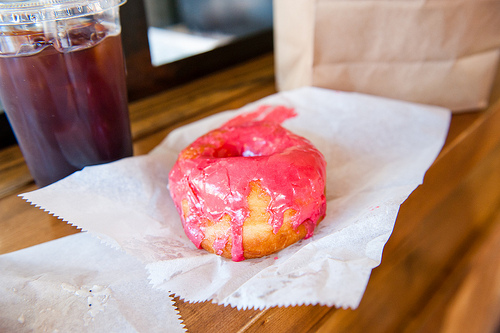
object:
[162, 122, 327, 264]
donut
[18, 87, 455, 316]
paper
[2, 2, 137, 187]
cup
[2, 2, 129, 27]
top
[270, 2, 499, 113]
bag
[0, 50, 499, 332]
table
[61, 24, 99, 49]
ice cube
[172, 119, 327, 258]
icing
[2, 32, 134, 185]
liquid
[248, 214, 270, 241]
part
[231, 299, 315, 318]
edge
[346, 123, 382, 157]
part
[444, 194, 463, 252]
part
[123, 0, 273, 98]
window